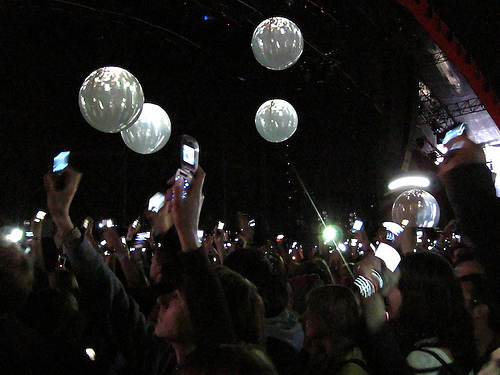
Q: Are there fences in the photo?
A: No, there are no fences.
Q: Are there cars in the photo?
A: No, there are no cars.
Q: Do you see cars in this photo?
A: No, there are no cars.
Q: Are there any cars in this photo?
A: No, there are no cars.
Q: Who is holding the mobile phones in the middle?
A: The people are holding the cell phones.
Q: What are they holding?
A: The people are holding the mobile phones.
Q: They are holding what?
A: The people are holding the mobile phones.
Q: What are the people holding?
A: The people are holding the mobile phones.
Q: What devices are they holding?
A: The people are holding the cellphones.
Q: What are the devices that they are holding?
A: The devices are cell phones.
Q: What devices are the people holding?
A: The people are holding the cellphones.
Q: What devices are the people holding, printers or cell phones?
A: The people are holding cell phones.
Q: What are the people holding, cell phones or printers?
A: The people are holding cell phones.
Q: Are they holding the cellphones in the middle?
A: Yes, the people are holding the mobile phones.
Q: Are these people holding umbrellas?
A: No, the people are holding the mobile phones.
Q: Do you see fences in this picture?
A: No, there are no fences.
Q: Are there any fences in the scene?
A: No, there are no fences.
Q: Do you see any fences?
A: No, there are no fences.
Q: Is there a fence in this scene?
A: No, there are no fences.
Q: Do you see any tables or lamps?
A: Yes, there is a lamp.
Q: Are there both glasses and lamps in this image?
A: No, there is a lamp but no glasses.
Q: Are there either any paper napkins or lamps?
A: Yes, there is a paper lamp.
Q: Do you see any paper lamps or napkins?
A: Yes, there is a paper lamp.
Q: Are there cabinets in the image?
A: No, there are no cabinets.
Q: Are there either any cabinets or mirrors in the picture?
A: No, there are no cabinets or mirrors.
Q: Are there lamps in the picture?
A: Yes, there is a lamp.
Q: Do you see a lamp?
A: Yes, there is a lamp.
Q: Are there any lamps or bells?
A: Yes, there is a lamp.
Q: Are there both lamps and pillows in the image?
A: No, there is a lamp but no pillows.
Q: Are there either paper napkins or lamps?
A: Yes, there is a paper lamp.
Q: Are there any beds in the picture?
A: No, there are no beds.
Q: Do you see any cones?
A: No, there are no cones.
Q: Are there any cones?
A: No, there are no cones.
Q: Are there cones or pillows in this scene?
A: No, there are no cones or pillows.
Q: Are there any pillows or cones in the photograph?
A: No, there are no cones or pillows.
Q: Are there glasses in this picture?
A: No, there are no glasses.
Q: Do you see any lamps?
A: Yes, there is a lamp.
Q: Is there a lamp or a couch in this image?
A: Yes, there is a lamp.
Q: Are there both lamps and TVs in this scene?
A: No, there is a lamp but no televisions.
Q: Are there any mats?
A: No, there are no mats.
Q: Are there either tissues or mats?
A: No, there are no mats or tissues.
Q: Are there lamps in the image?
A: Yes, there is a lamp.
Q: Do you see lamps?
A: Yes, there is a lamp.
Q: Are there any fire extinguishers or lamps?
A: Yes, there is a lamp.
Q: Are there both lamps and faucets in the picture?
A: No, there is a lamp but no faucets.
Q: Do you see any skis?
A: No, there are no skis.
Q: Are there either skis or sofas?
A: No, there are no skis or sofas.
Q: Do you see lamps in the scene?
A: Yes, there is a lamp.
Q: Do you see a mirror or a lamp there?
A: Yes, there is a lamp.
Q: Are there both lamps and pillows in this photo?
A: No, there is a lamp but no pillows.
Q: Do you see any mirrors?
A: No, there are no mirrors.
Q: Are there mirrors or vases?
A: No, there are no mirrors or vases.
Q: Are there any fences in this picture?
A: No, there are no fences.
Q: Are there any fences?
A: No, there are no fences.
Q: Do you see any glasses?
A: No, there are no glasses.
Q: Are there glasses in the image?
A: No, there are no glasses.